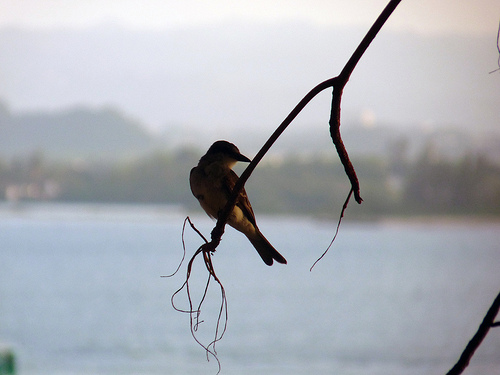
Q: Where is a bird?
A: On a branch.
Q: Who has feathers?
A: The bird.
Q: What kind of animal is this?
A: Bird.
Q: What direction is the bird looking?
A: To the right.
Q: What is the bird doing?
A: Sitting on tree branch.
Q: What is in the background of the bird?
A: Body of water.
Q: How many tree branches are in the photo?
A: Two.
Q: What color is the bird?
A: Brown and tan.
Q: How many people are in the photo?
A: None.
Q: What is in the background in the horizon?
A: Mountains and foliage.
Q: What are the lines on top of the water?
A: Ripples.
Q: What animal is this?
A: Bird.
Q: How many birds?
A: 1.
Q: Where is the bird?
A: Perched on a tree limb.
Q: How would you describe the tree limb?
A: Bare.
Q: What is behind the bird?
A: Lake.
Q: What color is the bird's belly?
A: White.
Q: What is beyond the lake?
A: Hills.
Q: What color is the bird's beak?
A: Black.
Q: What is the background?
A: Water.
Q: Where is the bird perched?
A: A branch.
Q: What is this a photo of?
A: A bird in a tree.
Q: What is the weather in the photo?
A: Cloudy.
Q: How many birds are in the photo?
A: One.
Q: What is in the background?
A: A body of water.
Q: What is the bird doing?
A: Perching.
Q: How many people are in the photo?
A: None.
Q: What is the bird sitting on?
A: Tree branch.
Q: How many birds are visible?
A: 1.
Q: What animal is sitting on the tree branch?
A: Bird.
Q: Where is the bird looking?
A: To the right.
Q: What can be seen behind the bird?
A: Ocean.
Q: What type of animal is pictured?
A: Bird.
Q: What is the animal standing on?
A: Tree branch.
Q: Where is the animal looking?
A: To its left.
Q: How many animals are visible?
A: One.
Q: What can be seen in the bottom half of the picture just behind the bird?
A: Water.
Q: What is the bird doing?
A: Standing on a branch.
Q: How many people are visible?
A: None.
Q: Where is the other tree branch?
A: Bottom right.